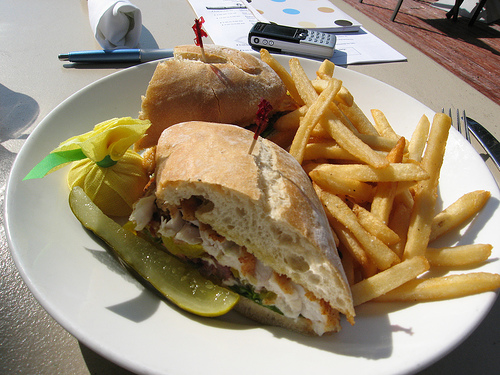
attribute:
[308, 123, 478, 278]
fries — golden, french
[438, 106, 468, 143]
fork — silver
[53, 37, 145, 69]
pen — silver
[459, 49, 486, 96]
floor — wooden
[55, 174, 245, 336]
pickle — cut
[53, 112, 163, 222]
sack — yellow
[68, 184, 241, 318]
green pickle — long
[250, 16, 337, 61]
cell phone — black and grey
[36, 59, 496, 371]
plate — white, full, round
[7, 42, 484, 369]
plate — full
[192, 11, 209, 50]
plastic top — red